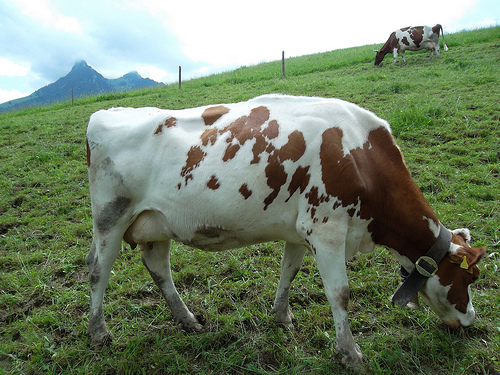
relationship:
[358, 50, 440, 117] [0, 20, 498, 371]
grass on hillside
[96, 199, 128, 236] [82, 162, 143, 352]
grey dirt on leg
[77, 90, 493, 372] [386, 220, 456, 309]
cow has grey collar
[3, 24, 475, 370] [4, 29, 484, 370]
grass in field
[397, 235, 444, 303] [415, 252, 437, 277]
collar has metal closure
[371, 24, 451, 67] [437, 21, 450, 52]
cow has tail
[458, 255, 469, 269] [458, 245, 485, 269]
tag in cows ear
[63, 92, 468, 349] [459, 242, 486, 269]
cow has ear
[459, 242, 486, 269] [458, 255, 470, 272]
ear has tag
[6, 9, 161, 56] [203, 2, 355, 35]
clouds in sky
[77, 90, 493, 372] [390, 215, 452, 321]
cow wearing collar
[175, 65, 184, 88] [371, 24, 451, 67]
fence post holds cow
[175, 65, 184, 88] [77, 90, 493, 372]
fence post holds cow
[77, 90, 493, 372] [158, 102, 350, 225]
cow has spots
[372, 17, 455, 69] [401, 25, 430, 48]
cow has spots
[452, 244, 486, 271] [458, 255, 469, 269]
ear has tag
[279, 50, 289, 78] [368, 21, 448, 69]
fence post behind cow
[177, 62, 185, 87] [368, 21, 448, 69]
fence post behind cow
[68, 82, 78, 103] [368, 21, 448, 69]
fence post behind cow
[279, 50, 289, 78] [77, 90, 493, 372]
fence post behind cow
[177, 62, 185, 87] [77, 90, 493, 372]
fence post behind cow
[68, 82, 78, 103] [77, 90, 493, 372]
fence post behind cow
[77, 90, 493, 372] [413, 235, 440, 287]
cow has collar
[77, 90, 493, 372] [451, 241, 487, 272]
cow has ear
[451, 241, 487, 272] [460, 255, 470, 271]
ear has tag